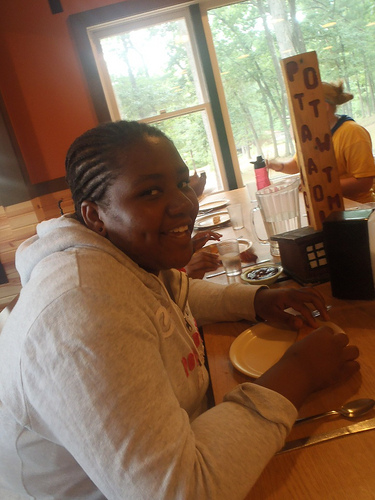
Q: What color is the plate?
A: White.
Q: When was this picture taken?
A: Daytime.